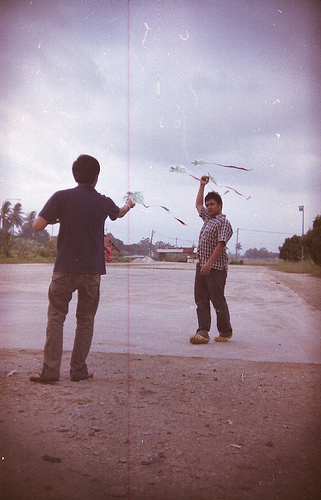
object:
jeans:
[194, 262, 233, 338]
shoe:
[188, 330, 210, 345]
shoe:
[214, 334, 233, 342]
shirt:
[197, 205, 233, 272]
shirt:
[37, 185, 120, 275]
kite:
[122, 190, 188, 227]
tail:
[143, 204, 188, 227]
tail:
[208, 171, 252, 200]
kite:
[169, 165, 229, 198]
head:
[72, 153, 100, 188]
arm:
[32, 192, 58, 232]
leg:
[70, 283, 100, 372]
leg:
[40, 289, 73, 378]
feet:
[29, 374, 60, 383]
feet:
[71, 372, 94, 381]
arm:
[109, 204, 129, 221]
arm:
[195, 184, 209, 222]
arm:
[209, 226, 234, 266]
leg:
[194, 265, 212, 330]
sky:
[0, 0, 316, 152]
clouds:
[41, 88, 136, 145]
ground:
[61, 383, 251, 457]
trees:
[0, 201, 60, 262]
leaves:
[4, 240, 46, 258]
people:
[28, 153, 136, 382]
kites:
[191, 159, 253, 171]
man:
[189, 175, 234, 344]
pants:
[40, 273, 101, 379]